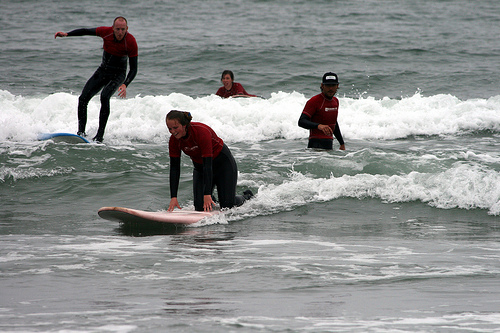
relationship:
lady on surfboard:
[164, 109, 256, 213] [91, 193, 221, 235]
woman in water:
[213, 66, 250, 98] [4, 0, 482, 330]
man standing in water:
[296, 71, 346, 151] [4, 0, 482, 330]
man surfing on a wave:
[35, 12, 142, 146] [6, 77, 491, 169]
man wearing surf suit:
[53, 16, 139, 144] [65, 26, 139, 144]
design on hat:
[322, 72, 336, 83] [318, 70, 340, 85]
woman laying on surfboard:
[215, 69, 266, 101] [94, 184, 268, 231]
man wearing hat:
[297, 71, 348, 151] [322, 67, 338, 84]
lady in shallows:
[164, 109, 256, 213] [285, 184, 405, 307]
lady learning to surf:
[157, 102, 259, 213] [100, 86, 288, 275]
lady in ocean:
[164, 109, 256, 213] [329, 180, 441, 297]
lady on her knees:
[164, 109, 256, 213] [194, 194, 238, 206]